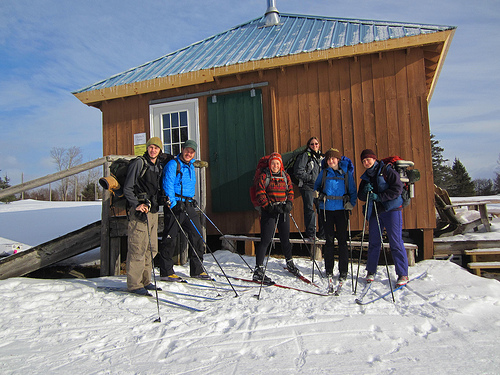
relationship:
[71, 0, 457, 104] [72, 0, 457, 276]
roof covering building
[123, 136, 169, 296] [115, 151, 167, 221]
man wears jacket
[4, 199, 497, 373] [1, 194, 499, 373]
snow covering ground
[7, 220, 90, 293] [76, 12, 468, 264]
ramp to building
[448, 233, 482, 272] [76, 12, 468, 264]
steps to building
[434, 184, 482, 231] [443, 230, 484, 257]
chair on deck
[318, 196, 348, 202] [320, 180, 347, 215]
strap around waist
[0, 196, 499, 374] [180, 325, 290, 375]
snow on ground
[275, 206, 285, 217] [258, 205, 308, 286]
hand on pole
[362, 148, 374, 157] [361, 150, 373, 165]
cap on head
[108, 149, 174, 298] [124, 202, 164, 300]
man wearing pants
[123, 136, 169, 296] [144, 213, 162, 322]
man with ski pole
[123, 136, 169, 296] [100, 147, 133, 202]
man with backpack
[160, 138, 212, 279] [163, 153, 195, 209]
man with jacket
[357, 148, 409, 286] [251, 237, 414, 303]
man with skis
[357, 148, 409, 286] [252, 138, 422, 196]
man with backpacks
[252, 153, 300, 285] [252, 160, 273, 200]
boy with backpack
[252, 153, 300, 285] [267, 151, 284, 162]
boy with hat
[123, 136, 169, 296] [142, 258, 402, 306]
man with skis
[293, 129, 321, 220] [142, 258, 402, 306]
one person without skis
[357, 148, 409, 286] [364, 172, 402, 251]
man dressedwearing blue clothes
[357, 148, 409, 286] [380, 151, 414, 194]
man with backpack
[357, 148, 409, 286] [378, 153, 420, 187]
man with backpack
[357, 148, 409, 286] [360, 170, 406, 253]
man dressed inwearing blue clothes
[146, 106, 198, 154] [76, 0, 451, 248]
door on building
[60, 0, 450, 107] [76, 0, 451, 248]
roof on building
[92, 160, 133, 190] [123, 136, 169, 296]
backpack on man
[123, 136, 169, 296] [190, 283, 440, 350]
man on snow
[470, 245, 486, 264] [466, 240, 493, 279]
snow on steps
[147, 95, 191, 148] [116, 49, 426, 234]
window on building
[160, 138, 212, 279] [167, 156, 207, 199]
man wearing jacket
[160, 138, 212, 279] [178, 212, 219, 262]
man wearing pants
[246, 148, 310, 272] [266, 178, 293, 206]
boy wearing sweater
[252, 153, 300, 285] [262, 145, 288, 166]
boy wearing hat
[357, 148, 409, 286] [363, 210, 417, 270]
man wearing pants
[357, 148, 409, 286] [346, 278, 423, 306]
man wearing skis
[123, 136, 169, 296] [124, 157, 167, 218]
man wearing jacket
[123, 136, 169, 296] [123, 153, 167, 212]
man wearing jacket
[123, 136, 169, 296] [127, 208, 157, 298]
man with pants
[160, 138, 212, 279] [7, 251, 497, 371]
man standing on snow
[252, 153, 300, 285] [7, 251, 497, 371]
boy standing on snow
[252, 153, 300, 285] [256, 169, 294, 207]
boy wearing a jacket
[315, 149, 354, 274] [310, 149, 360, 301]
person wearing a sport kit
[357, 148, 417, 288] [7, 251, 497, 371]
man standing on snow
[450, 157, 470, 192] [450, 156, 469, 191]
leaves on tree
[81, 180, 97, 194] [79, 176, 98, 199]
leaves on tree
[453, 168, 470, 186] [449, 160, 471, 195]
leaves on tree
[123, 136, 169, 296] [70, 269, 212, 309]
man on skis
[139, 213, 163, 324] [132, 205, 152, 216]
ski pole in a hand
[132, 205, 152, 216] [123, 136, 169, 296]
hand of a man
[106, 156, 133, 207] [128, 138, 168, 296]
backpack on a man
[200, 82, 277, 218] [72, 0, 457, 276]
door on a building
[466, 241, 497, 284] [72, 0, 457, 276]
stairs to a building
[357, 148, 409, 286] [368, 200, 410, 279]
man weaing pants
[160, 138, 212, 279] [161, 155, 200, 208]
man has jacket